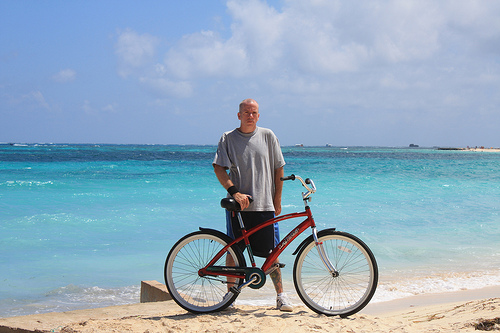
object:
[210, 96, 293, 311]
man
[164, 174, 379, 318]
bike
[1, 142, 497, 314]
ocean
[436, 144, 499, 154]
island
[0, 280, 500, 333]
beach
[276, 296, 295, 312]
shoe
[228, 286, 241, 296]
pedal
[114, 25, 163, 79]
cloud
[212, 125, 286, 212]
shirt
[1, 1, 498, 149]
sky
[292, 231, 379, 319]
wheel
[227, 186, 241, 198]
armband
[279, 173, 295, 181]
handle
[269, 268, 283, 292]
tattoo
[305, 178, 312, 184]
bars